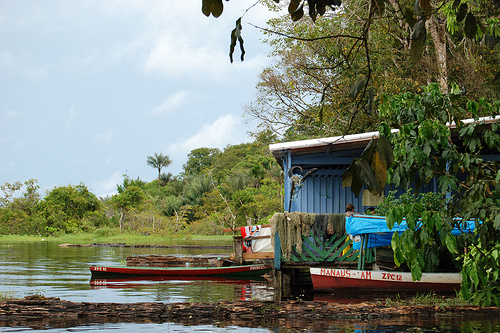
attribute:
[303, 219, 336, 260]
net — hanging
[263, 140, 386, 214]
house — wooden, blue, big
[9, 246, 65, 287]
river — calm, rippling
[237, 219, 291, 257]
dock — wooden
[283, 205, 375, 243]
clothes — hanging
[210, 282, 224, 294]
water — cool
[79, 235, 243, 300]
boat — re, red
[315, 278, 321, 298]
paint — white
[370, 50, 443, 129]
tree — palm, group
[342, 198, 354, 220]
person — sitting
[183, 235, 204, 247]
shoreline — small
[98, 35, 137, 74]
sky — blue, blu